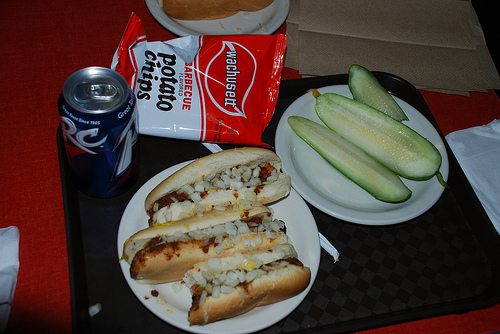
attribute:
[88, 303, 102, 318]
onion — white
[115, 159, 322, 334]
plate — white, round, circular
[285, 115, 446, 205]
pickle — green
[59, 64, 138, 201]
can — blue, aluminum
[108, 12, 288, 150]
bag — red, barbeque, white, small, open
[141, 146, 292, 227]
hot dog — covered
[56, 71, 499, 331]
tray — black, plastic, large, dark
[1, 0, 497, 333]
table — red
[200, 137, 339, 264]
straw — white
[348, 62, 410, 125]
pickle — half-eaten, partially eaten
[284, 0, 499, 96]
towels — brown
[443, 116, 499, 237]
napkin — white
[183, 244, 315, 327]
chili dog — bitten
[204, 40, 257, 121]
logo — white